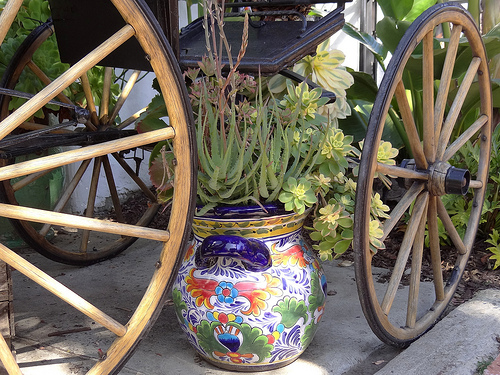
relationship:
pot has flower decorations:
[168, 202, 332, 370] [186, 267, 283, 317]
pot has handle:
[168, 202, 332, 370] [194, 231, 270, 272]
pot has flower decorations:
[168, 202, 332, 370] [190, 316, 272, 362]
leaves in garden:
[485, 227, 499, 263] [399, 5, 499, 245]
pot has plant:
[168, 202, 332, 370] [183, 48, 397, 255]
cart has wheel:
[46, 1, 351, 75] [355, 5, 492, 348]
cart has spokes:
[46, 1, 351, 75] [428, 27, 482, 157]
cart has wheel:
[46, 1, 351, 75] [1, 1, 203, 373]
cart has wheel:
[46, 1, 351, 75] [2, 22, 161, 267]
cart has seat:
[46, 1, 351, 75] [173, 19, 342, 64]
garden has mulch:
[399, 5, 499, 245] [465, 253, 499, 292]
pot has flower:
[168, 202, 332, 370] [281, 81, 333, 126]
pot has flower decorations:
[168, 202, 332, 370] [206, 259, 256, 280]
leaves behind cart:
[348, 8, 412, 142] [46, 1, 351, 75]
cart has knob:
[46, 1, 351, 75] [437, 164, 476, 195]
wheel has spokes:
[355, 5, 492, 348] [428, 27, 482, 157]